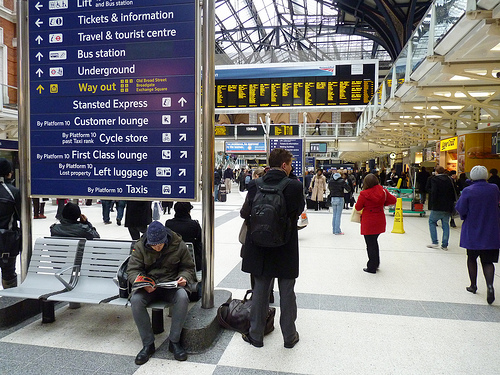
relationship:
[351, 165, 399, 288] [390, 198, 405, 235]
woman wearing cone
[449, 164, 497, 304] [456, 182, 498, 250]
woman wearing coat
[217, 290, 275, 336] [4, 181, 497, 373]
bag on floor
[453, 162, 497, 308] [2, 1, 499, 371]
person in station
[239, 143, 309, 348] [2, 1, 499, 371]
person in station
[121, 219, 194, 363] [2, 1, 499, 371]
person in station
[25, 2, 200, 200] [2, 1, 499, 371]
sign in station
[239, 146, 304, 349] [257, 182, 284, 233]
person has backpack